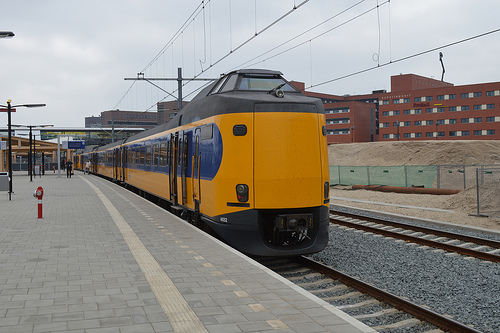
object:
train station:
[0, 32, 500, 333]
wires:
[110, 0, 500, 123]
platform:
[0, 178, 100, 333]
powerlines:
[90, 0, 499, 138]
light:
[27, 103, 48, 108]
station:
[11, 125, 86, 187]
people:
[61, 159, 91, 179]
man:
[84, 160, 92, 175]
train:
[148, 90, 343, 265]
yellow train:
[75, 112, 329, 219]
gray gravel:
[259, 202, 498, 333]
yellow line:
[232, 288, 248, 298]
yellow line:
[247, 303, 267, 313]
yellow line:
[192, 252, 205, 260]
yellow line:
[174, 239, 183, 244]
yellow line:
[264, 319, 290, 331]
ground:
[0, 239, 223, 329]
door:
[183, 128, 200, 213]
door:
[169, 132, 178, 204]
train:
[70, 67, 332, 259]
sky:
[34, 10, 143, 48]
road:
[26, 190, 95, 331]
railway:
[253, 208, 500, 333]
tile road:
[0, 170, 211, 330]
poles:
[0, 98, 47, 194]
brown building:
[287, 72, 500, 143]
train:
[149, 71, 348, 280]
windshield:
[239, 77, 297, 91]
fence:
[327, 165, 500, 189]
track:
[253, 200, 500, 332]